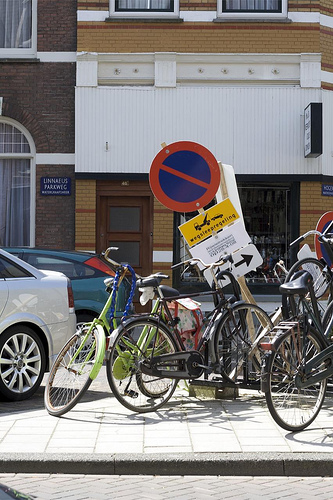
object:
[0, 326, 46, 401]
wheel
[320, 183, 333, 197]
sign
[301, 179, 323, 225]
brick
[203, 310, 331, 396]
bike rack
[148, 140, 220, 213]
sign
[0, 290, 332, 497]
street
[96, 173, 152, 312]
door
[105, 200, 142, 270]
windows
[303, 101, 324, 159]
electrical sign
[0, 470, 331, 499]
brick pavement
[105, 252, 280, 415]
bike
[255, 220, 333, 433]
bike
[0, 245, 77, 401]
car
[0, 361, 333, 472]
sidewalk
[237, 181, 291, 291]
mirror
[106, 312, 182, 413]
tire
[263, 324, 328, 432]
tire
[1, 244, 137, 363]
car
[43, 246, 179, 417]
bicycle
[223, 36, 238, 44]
brick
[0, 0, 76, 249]
brick building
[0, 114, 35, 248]
window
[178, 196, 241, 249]
sign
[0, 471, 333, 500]
red brick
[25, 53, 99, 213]
wall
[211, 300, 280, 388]
tire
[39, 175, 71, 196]
sign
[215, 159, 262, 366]
post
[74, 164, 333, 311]
building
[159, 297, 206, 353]
box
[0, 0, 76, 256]
brick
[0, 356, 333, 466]
pavement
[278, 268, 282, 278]
dog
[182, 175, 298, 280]
reflection